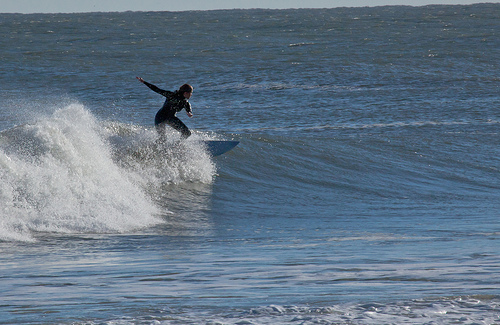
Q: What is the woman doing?
A: Surfing.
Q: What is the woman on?
A: Surfboard.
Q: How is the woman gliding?
A: A wave.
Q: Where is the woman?
A: Ocean.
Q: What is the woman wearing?
A: Wetsuit.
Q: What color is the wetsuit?
A: Black.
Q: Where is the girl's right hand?
A: In the air.